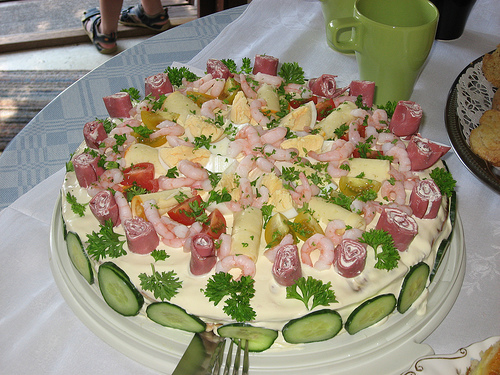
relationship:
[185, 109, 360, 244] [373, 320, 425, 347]
cookies on tray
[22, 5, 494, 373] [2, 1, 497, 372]
tablecloth on table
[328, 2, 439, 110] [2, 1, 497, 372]
coffee cup on table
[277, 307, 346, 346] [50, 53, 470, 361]
cucumber on cake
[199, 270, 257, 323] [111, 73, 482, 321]
leaf on cake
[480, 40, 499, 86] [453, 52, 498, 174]
cookies on doily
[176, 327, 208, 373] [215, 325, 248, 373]
knife by fork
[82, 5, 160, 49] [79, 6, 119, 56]
feet in sandal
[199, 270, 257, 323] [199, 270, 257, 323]
leaf of leaf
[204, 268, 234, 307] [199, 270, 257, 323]
leaf of leaf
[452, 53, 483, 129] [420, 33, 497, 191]
doily on silver plate